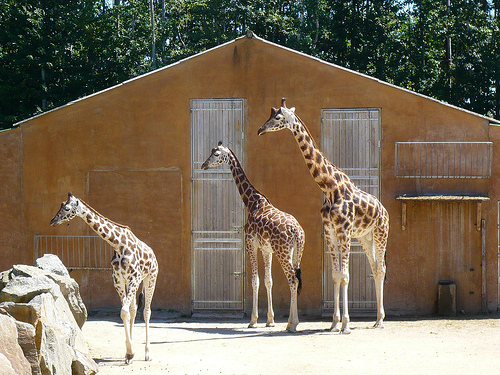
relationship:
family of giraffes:
[49, 92, 398, 375] [46, 94, 388, 361]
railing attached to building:
[392, 135, 496, 183] [3, 28, 499, 327]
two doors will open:
[183, 93, 391, 326] [335, 128, 377, 161]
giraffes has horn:
[256, 97, 391, 336] [274, 95, 291, 108]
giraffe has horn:
[48, 192, 159, 368] [64, 189, 83, 198]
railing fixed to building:
[392, 135, 496, 183] [3, 28, 499, 327]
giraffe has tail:
[43, 186, 176, 368] [136, 281, 146, 314]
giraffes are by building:
[46, 94, 388, 361] [3, 28, 499, 327]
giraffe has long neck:
[43, 186, 176, 368] [81, 203, 119, 248]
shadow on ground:
[149, 321, 267, 339] [90, 309, 500, 373]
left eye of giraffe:
[60, 205, 76, 213] [43, 186, 176, 368]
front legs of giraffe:
[110, 269, 139, 364] [43, 186, 176, 368]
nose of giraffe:
[47, 215, 58, 225] [43, 186, 176, 368]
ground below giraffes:
[90, 309, 500, 373] [46, 94, 388, 361]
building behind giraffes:
[3, 28, 499, 327] [46, 94, 388, 361]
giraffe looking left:
[48, 192, 159, 368] [17, 194, 46, 235]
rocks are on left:
[3, 245, 101, 374] [17, 194, 46, 235]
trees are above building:
[2, 5, 499, 129] [3, 28, 499, 327]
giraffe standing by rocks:
[48, 192, 159, 368] [3, 245, 101, 374]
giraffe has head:
[43, 186, 176, 368] [45, 191, 81, 230]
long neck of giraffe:
[81, 203, 119, 248] [43, 186, 176, 368]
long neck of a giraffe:
[81, 203, 119, 248] [43, 186, 176, 368]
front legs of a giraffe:
[110, 269, 139, 364] [43, 186, 176, 368]